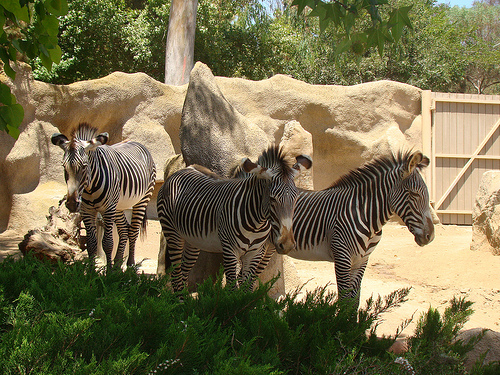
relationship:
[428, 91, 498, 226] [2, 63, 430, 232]
door on fence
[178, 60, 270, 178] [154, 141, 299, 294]
rock behind zebra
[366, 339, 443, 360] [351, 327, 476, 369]
trash on floor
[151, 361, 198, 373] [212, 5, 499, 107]
pine cone on trees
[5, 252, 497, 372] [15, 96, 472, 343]
bush growing pen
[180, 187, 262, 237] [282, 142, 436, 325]
stripes on zebra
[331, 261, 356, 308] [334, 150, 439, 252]
leg of zebra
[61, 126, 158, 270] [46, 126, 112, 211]
zebra has head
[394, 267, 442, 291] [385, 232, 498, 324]
dirt on ground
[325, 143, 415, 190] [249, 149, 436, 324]
hair on zebra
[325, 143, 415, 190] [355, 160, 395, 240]
hair on neck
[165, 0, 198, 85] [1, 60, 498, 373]
tree outside pen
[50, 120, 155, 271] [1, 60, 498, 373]
zebras standing in pen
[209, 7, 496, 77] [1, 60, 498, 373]
trees growing outside of pen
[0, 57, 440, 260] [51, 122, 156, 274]
boulder behind zebra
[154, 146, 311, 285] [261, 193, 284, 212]
zebra has eye